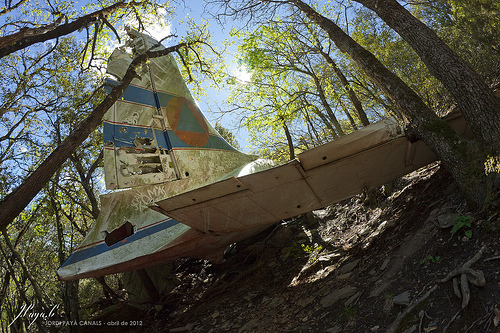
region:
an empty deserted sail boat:
[22, 20, 439, 248]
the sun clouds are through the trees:
[205, 12, 312, 131]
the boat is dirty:
[58, 10, 318, 267]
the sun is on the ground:
[293, 194, 390, 275]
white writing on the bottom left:
[7, 290, 156, 329]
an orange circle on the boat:
[162, 84, 208, 147]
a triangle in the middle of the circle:
[162, 90, 207, 141]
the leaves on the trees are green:
[233, 22, 320, 137]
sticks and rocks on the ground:
[255, 241, 474, 311]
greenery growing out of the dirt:
[414, 192, 489, 270]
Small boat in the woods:
[34, 43, 430, 276]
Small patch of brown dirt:
[164, 295, 219, 324]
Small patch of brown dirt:
[212, 283, 254, 324]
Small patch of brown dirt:
[247, 296, 279, 331]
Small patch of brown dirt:
[256, 249, 295, 292]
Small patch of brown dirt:
[296, 233, 353, 260]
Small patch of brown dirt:
[334, 204, 404, 232]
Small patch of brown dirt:
[356, 223, 424, 291]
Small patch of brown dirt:
[267, 273, 357, 320]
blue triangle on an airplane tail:
[163, 92, 213, 152]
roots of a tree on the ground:
[334, 235, 489, 328]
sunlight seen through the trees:
[227, 21, 289, 128]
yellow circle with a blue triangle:
[161, 86, 218, 153]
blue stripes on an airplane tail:
[95, 63, 222, 160]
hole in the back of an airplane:
[98, 200, 138, 260]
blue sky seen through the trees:
[152, 10, 287, 109]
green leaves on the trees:
[350, 20, 435, 92]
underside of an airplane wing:
[152, 177, 367, 225]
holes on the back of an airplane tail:
[117, 122, 171, 192]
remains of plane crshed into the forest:
[58, 23, 495, 293]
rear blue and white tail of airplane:
[96, 25, 229, 190]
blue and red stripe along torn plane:
[64, 213, 176, 272]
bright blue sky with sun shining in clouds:
[0, 4, 447, 196]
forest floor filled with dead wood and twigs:
[166, 195, 498, 328]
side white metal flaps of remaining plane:
[146, 98, 491, 234]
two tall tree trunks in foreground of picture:
[3, 3, 231, 235]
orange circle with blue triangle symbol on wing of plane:
[161, 88, 216, 153]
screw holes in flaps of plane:
[186, 180, 244, 205]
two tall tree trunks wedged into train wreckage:
[288, 0, 499, 226]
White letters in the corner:
[6, 294, 154, 331]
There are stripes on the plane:
[41, 22, 440, 298]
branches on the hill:
[319, 219, 494, 331]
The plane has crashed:
[48, 21, 498, 261]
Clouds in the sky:
[83, 7, 207, 91]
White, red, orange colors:
[88, 28, 253, 200]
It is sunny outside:
[176, 13, 298, 113]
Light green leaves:
[228, 23, 325, 130]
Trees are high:
[310, 9, 499, 221]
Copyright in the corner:
[11, 292, 151, 332]